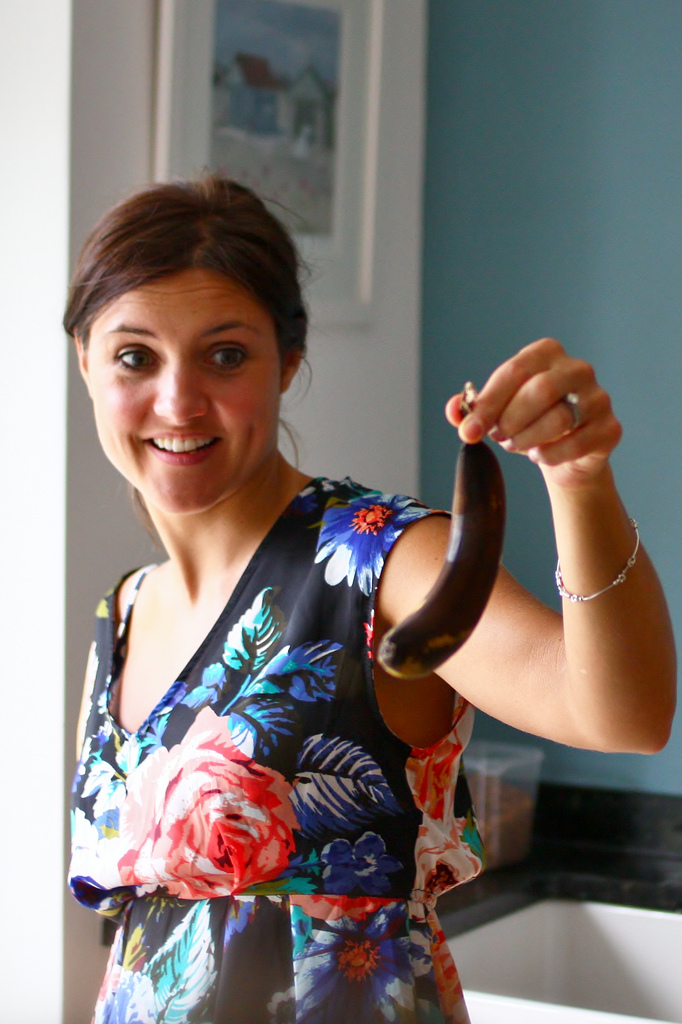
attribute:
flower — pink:
[134, 748, 305, 907]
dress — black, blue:
[66, 472, 488, 1021]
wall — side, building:
[13, 750, 99, 984]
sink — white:
[420, 889, 661, 1021]